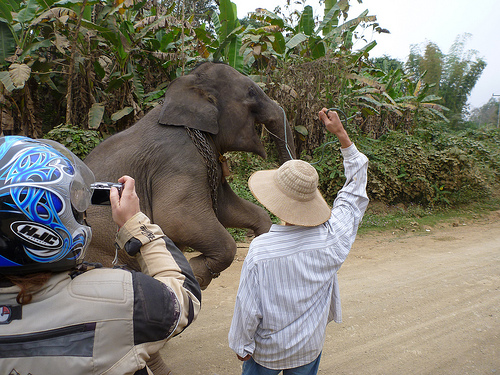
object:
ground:
[398, 268, 480, 368]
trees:
[0, 0, 77, 127]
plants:
[0, 0, 499, 204]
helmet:
[0, 136, 95, 274]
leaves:
[25, 3, 77, 29]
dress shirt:
[234, 143, 371, 367]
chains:
[186, 127, 220, 215]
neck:
[209, 133, 229, 154]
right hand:
[109, 175, 139, 223]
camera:
[87, 181, 124, 206]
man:
[235, 106, 370, 361]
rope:
[264, 105, 361, 165]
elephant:
[38, 61, 297, 374]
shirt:
[0, 212, 201, 374]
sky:
[351, 0, 499, 108]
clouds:
[389, 7, 416, 29]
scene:
[0, 0, 499, 374]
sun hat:
[248, 159, 331, 226]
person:
[0, 135, 201, 374]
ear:
[157, 74, 219, 134]